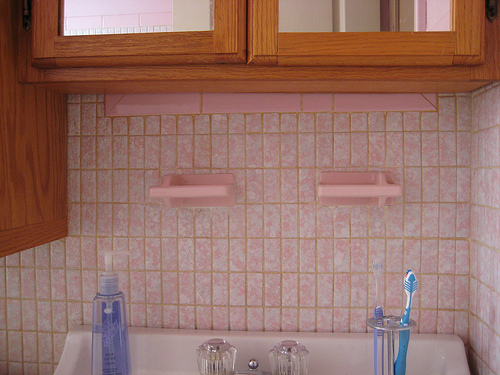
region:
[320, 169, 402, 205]
a pink soap holder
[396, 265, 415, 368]
a blue toothbrush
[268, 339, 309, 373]
a water knob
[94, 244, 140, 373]
a soap dispenser bottle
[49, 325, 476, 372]
a white bathroom sink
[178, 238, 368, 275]
small rectangular pink ceramic tiles.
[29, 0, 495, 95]
a two door wooden cabinet.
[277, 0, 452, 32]
mirror on a door cabinet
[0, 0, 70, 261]
a larger wooden cabinet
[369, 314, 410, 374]
a metal toothbrush holder.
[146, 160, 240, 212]
Pink soap dish on the wall.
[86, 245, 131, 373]
Hand soap sitting on the sink.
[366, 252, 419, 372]
Toothbrush holder holding two toothbrushes.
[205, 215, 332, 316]
Pink tile on the wall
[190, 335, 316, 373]
Bathroom sink faucet knobs.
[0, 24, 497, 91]
Bathroom medicine cabinet.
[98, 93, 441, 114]
Pink tile below the cabinet.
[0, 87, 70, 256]
Side of the medicine cabinet.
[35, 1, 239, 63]
Mirror on the medicine cabinet door.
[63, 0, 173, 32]
Reflection of the pink tile in the mirror.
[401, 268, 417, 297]
The head of a tooth brush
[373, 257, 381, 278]
The transparent head of a tooth brush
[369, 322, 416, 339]
A tooth brush holder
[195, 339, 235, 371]
A clear tap handle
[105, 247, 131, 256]
The spout of a soap dispenser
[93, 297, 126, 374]
A soap bottle on the basin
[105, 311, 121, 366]
Blue liquid soap in the bottle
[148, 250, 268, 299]
Tiles in the bathroom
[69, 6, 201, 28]
A mirror with a reflection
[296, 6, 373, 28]
A mirror reflecting the door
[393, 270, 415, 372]
Blue toothbrush in holder.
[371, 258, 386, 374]
Clear and purple toothbrush.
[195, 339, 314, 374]
Clear sink handles.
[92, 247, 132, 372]
Clear bottle of hand soap.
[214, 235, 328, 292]
Pink and white tiled wall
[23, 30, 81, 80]
Part of the cupboard.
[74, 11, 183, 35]
Part of the glass cupboard.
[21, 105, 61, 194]
The cupboard is made of wood.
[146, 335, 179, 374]
Part of the white sink.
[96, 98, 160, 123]
Part of the pink tiled wall.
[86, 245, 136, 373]
plastic soap dispenser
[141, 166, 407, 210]
matching pair of pink soap trays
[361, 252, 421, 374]
two toothbrushes in a chrome toothbrush holder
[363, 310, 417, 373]
chrome toothbrush holder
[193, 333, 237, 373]
hot water tap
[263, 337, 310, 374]
cold water tap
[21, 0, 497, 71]
doors on the bathroom cupboard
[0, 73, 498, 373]
pale pink tiled wall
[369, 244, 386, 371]
blue and clear toothbrush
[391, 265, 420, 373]
blue and white toothbrush